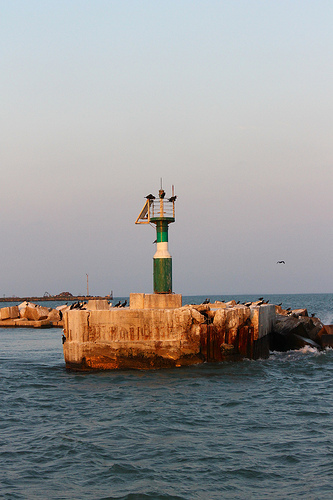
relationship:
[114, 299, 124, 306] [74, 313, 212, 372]
bird on rock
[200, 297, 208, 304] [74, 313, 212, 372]
bird on rock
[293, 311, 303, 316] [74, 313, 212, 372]
bird on rock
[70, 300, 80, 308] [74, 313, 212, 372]
bird on rock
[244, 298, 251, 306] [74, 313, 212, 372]
bird on rock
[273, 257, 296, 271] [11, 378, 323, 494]
bird over water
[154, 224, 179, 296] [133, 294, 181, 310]
structure on base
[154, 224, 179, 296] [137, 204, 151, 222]
structure with instrument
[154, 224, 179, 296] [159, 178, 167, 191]
structure with antennae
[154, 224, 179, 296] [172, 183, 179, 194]
structure with antennae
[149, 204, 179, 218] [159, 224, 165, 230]
railing on top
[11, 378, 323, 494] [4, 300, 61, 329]
water against rock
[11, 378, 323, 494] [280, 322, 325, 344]
water against rock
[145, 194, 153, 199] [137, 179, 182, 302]
bird on buoy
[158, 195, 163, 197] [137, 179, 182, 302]
bird on buoy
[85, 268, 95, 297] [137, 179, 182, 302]
crane behind buoy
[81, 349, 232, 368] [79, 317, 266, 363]
stains on wall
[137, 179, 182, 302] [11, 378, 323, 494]
dock in water